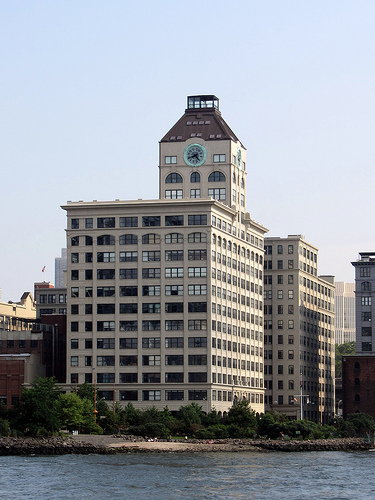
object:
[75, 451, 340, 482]
water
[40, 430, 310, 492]
dark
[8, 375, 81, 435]
green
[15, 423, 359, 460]
rocks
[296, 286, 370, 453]
right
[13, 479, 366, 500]
water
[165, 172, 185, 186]
half-circles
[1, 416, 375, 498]
lake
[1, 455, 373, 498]
dark water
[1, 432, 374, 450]
coastline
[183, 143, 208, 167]
clock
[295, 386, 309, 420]
pole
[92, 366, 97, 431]
pole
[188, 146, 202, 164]
gray black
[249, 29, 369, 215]
white clouds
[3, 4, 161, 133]
blue sky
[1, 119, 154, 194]
white clouds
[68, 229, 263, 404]
many windows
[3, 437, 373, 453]
rocky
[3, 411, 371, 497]
coast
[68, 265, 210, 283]
row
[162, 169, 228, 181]
circular windows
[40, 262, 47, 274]
flag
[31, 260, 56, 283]
distance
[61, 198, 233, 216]
roof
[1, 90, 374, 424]
several buildings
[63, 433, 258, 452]
walkway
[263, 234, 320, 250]
roof